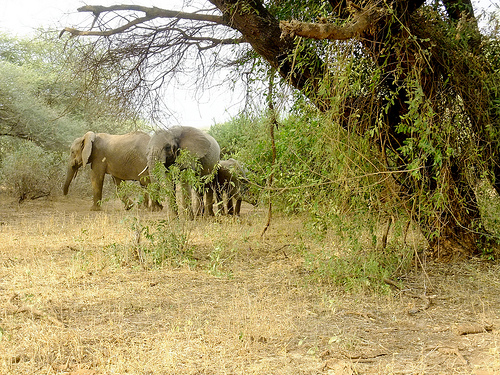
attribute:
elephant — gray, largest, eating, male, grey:
[140, 118, 221, 214]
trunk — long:
[151, 169, 158, 211]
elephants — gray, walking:
[59, 118, 243, 199]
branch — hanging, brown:
[220, 3, 389, 135]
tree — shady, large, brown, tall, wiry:
[70, 1, 499, 250]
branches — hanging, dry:
[76, 1, 373, 121]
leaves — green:
[286, 27, 477, 196]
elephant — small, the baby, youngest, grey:
[200, 165, 262, 209]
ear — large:
[81, 133, 98, 168]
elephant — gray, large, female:
[64, 131, 151, 209]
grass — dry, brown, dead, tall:
[6, 203, 499, 370]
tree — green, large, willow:
[2, 34, 125, 202]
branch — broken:
[275, 8, 363, 41]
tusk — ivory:
[135, 165, 148, 178]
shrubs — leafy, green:
[2, 109, 400, 287]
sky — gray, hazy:
[4, 6, 280, 132]